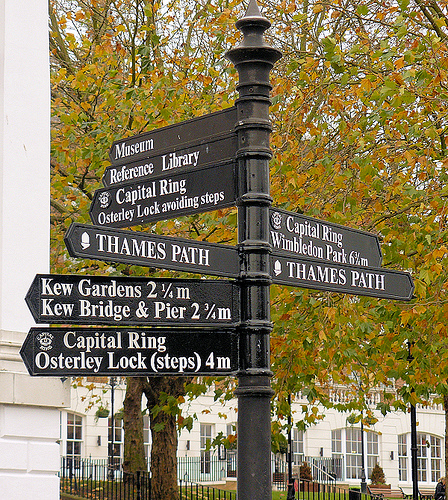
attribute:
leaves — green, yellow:
[327, 88, 375, 162]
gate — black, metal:
[61, 461, 143, 498]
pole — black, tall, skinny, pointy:
[227, 22, 274, 495]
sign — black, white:
[261, 206, 386, 264]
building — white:
[72, 373, 447, 491]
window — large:
[65, 411, 81, 469]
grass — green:
[185, 480, 233, 492]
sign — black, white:
[69, 225, 237, 270]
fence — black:
[278, 484, 362, 500]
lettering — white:
[121, 147, 142, 151]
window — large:
[331, 427, 390, 487]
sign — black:
[38, 339, 232, 373]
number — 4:
[197, 340, 233, 369]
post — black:
[284, 397, 306, 496]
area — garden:
[207, 473, 401, 498]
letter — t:
[89, 232, 109, 253]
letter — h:
[109, 235, 122, 256]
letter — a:
[119, 236, 131, 258]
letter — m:
[131, 232, 147, 260]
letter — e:
[148, 243, 156, 260]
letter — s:
[157, 240, 169, 261]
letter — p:
[172, 244, 182, 267]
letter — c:
[57, 328, 78, 353]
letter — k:
[43, 280, 56, 296]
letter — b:
[80, 299, 93, 320]